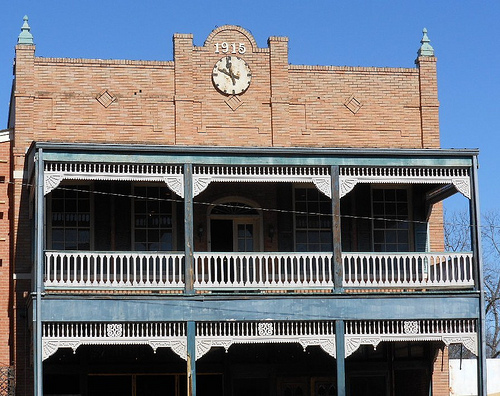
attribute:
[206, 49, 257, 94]
clock —  antique public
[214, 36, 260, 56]
number —  1915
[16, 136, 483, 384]
finial —  green patina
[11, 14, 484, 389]
building — old brick, brown, door, Windows, brick, wood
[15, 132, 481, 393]
balcony —  outdoor shaded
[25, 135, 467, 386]
railing — white wood, stretch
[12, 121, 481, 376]
railing — white wood , stretch 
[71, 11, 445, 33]
sky — deep blue 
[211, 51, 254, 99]
building — clock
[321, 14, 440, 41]
sky — clear blue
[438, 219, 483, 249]
branches — Tree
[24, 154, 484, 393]
house — Blue poles 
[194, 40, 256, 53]
building — numbers 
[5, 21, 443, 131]
building — Windows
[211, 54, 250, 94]
clock — big, old, analog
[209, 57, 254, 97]
clock — analog, big, old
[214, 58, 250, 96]
clock — white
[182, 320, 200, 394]
board — blue, wooden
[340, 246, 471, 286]
railing — white